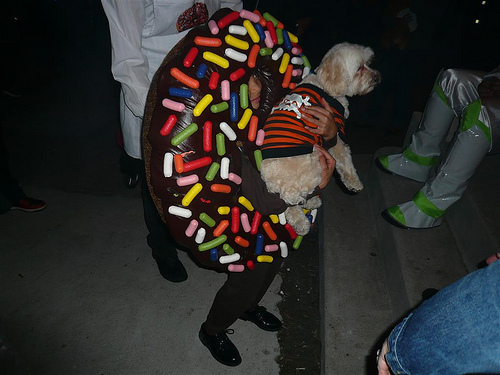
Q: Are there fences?
A: No, there are no fences.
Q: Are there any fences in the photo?
A: No, there are no fences.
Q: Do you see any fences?
A: No, there are no fences.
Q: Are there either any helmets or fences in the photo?
A: No, there are no fences or helmets.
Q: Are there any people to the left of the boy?
A: Yes, there is a person to the left of the boy.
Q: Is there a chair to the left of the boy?
A: No, there is a person to the left of the boy.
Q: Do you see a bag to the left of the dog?
A: No, there is a person to the left of the dog.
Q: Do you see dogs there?
A: Yes, there is a dog.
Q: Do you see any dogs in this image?
A: Yes, there is a dog.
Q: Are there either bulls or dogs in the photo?
A: Yes, there is a dog.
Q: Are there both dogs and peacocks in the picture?
A: No, there is a dog but no peacocks.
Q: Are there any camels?
A: No, there are no camels.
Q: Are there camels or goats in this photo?
A: No, there are no camels or goats.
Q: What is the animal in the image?
A: The animal is a dog.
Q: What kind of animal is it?
A: The animal is a dog.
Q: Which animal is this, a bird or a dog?
A: This is a dog.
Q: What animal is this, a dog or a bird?
A: This is a dog.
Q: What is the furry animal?
A: The animal is a dog.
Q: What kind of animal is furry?
A: The animal is a dog.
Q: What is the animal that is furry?
A: The animal is a dog.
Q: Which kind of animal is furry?
A: The animal is a dog.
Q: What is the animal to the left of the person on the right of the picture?
A: The animal is a dog.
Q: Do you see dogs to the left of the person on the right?
A: Yes, there is a dog to the left of the person.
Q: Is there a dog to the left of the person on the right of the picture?
A: Yes, there is a dog to the left of the person.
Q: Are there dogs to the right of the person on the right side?
A: No, the dog is to the left of the person.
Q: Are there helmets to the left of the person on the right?
A: No, there is a dog to the left of the person.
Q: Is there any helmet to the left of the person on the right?
A: No, there is a dog to the left of the person.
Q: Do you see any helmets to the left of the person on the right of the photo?
A: No, there is a dog to the left of the person.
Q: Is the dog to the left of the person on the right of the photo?
A: Yes, the dog is to the left of the person.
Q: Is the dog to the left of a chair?
A: No, the dog is to the left of the person.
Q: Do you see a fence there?
A: No, there are no fences.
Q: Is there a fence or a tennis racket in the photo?
A: No, there are no fences or rackets.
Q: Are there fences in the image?
A: No, there are no fences.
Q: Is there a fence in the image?
A: No, there are no fences.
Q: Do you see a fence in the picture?
A: No, there are no fences.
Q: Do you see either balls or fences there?
A: No, there are no fences or balls.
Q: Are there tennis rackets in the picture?
A: No, there are no tennis rackets.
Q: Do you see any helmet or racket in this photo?
A: No, there are no rackets or helmets.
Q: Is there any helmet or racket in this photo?
A: No, there are no rackets or helmets.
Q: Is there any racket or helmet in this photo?
A: No, there are no rackets or helmets.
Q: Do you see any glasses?
A: No, there are no glasses.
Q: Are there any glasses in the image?
A: No, there are no glasses.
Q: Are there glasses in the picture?
A: No, there are no glasses.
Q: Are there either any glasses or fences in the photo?
A: No, there are no glasses or fences.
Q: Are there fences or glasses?
A: No, there are no glasses or fences.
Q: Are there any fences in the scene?
A: No, there are no fences.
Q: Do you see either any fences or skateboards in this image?
A: No, there are no fences or skateboards.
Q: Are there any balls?
A: No, there are no balls.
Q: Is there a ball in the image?
A: No, there are no balls.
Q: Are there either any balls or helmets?
A: No, there are no balls or helmets.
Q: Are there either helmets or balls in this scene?
A: No, there are no balls or helmets.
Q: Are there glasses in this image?
A: No, there are no glasses.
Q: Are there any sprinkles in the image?
A: Yes, there are sprinkles.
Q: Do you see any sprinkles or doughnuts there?
A: Yes, there are sprinkles.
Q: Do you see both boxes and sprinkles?
A: No, there are sprinkles but no boxes.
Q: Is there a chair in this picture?
A: No, there are no chairs.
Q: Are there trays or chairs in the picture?
A: No, there are no chairs or trays.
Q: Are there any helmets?
A: No, there are no helmets.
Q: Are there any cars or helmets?
A: No, there are no helmets or cars.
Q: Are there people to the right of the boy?
A: Yes, there is a person to the right of the boy.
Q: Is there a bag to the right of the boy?
A: No, there is a person to the right of the boy.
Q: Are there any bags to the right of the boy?
A: No, there is a person to the right of the boy.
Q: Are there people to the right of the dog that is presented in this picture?
A: Yes, there is a person to the right of the dog.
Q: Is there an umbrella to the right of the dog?
A: No, there is a person to the right of the dog.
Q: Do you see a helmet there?
A: No, there are no helmets.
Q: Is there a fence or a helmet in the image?
A: No, there are no helmets or fences.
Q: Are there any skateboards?
A: No, there are no skateboards.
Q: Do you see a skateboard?
A: No, there are no skateboards.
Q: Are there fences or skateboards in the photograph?
A: No, there are no skateboards or fences.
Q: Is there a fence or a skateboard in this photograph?
A: No, there are no skateboards or fences.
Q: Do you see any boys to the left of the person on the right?
A: Yes, there is a boy to the left of the person.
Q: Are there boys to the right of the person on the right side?
A: No, the boy is to the left of the person.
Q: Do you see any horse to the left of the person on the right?
A: No, there is a boy to the left of the person.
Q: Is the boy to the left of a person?
A: Yes, the boy is to the left of a person.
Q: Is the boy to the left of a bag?
A: No, the boy is to the left of a person.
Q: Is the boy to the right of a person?
A: No, the boy is to the left of a person.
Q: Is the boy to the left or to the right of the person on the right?
A: The boy is to the left of the person.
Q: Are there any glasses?
A: No, there are no glasses.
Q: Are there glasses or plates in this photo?
A: No, there are no glasses or plates.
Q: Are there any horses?
A: No, there are no horses.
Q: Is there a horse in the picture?
A: No, there are no horses.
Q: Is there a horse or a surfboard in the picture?
A: No, there are no horses or surfboards.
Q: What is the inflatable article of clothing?
A: The clothing item is a costume.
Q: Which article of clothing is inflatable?
A: The clothing item is a costume.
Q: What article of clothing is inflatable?
A: The clothing item is a costume.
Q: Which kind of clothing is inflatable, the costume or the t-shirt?
A: The costume is inflatable.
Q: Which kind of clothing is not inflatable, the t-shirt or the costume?
A: The t-shirt is not inflatable.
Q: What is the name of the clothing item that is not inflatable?
A: The clothing item is a t-shirt.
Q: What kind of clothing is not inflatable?
A: The clothing is a t-shirt.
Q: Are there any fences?
A: No, there are no fences.